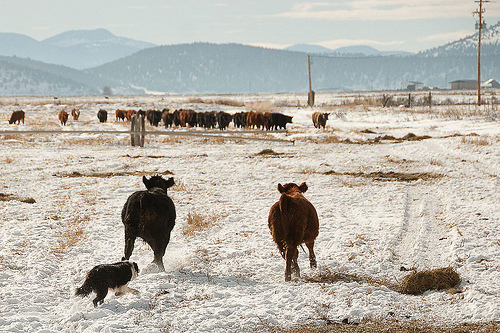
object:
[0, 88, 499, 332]
pasture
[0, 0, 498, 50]
sky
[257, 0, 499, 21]
clouds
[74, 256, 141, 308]
dog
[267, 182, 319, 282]
cow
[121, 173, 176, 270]
cow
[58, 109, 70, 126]
cows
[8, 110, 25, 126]
cow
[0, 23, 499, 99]
mountain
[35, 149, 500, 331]
snow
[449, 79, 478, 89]
building